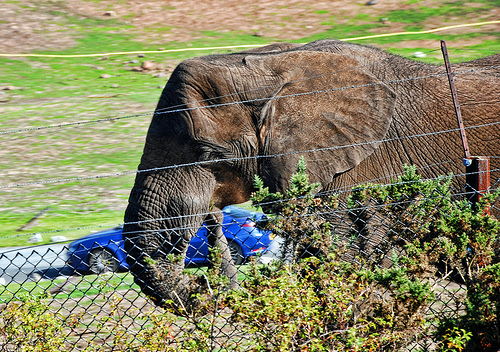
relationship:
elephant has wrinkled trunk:
[115, 32, 499, 349] [116, 153, 244, 325]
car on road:
[58, 194, 282, 277] [0, 243, 475, 331]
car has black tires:
[58, 194, 282, 277] [83, 245, 245, 276]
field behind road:
[1, 6, 498, 51] [0, 243, 475, 331]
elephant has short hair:
[115, 32, 499, 349] [197, 38, 367, 60]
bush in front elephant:
[0, 169, 496, 350] [115, 32, 499, 349]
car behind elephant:
[58, 194, 282, 277] [115, 32, 499, 349]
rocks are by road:
[0, 224, 73, 289] [0, 243, 475, 331]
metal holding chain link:
[435, 33, 491, 346] [2, 41, 500, 352]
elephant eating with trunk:
[115, 32, 499, 349] [116, 153, 244, 325]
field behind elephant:
[1, 6, 498, 51] [115, 32, 499, 349]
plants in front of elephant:
[0, 169, 496, 350] [115, 32, 499, 349]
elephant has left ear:
[115, 32, 499, 349] [242, 48, 406, 199]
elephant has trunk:
[115, 32, 499, 349] [116, 153, 244, 325]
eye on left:
[187, 140, 220, 172] [215, 146, 242, 168]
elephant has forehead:
[115, 32, 499, 349] [143, 63, 191, 155]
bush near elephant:
[0, 169, 496, 350] [115, 32, 499, 349]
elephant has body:
[115, 32, 499, 349] [254, 36, 499, 245]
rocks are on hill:
[91, 45, 171, 89] [5, 2, 178, 81]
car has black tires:
[58, 194, 282, 277] [88, 248, 120, 275]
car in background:
[58, 194, 282, 277] [3, 8, 130, 267]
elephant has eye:
[115, 32, 499, 349] [187, 140, 220, 172]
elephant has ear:
[115, 32, 499, 349] [242, 48, 406, 199]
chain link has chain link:
[2, 41, 500, 352] [2, 73, 498, 167]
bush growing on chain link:
[0, 169, 496, 350] [2, 41, 500, 352]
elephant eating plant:
[115, 32, 499, 349] [201, 168, 345, 343]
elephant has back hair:
[115, 32, 499, 349] [176, 34, 401, 68]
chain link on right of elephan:
[2, 41, 500, 352] [115, 32, 499, 349]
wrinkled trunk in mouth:
[116, 153, 244, 325] [195, 191, 226, 226]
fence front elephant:
[115, 32, 499, 349] [123, 38, 499, 349]